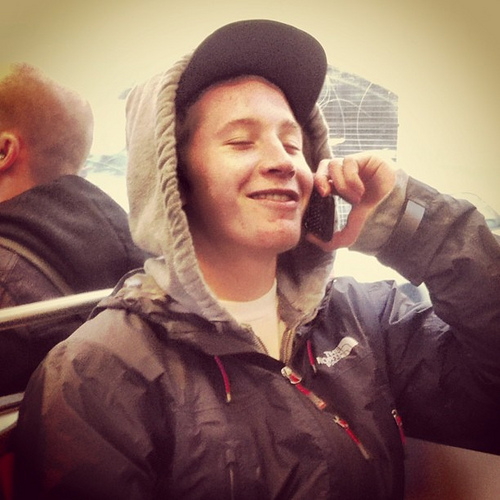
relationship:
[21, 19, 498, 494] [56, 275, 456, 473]
boy in jacket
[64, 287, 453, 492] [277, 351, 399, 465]
jacket has zippers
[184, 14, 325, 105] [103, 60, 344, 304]
cap under hood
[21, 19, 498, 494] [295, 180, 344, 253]
boy holding phone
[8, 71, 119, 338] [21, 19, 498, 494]
man back to boy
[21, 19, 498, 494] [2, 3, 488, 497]
boy picture picture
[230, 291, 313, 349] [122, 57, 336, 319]
shirt under hoodie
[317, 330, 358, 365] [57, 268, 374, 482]
logo on jacket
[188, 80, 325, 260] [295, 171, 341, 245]
man talking on phone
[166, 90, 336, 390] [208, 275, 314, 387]
person wearing shirt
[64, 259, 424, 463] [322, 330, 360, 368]
breaker with logo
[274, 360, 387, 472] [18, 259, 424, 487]
zipper on breaker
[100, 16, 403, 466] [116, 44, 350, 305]
man wearing hoodie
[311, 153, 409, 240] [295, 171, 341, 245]
hand holding phone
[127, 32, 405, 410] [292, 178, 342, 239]
man holding phone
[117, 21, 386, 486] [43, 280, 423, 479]
man wearing jacket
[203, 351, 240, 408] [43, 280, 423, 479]
string for jacket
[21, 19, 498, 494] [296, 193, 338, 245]
boy on phone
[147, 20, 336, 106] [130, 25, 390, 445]
hat worn by man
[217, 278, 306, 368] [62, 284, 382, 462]
shirt underneath jacket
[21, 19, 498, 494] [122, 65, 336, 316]
boy wearing hood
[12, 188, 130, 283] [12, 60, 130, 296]
hood for guy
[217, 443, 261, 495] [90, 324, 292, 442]
zipper in front of jacket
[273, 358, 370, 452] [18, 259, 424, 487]
zipper on breaker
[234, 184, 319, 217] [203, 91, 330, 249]
grin on face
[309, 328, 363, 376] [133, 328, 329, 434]
logo on jacket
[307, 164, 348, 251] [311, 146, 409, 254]
cell phone in hand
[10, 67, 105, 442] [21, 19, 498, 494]
man behind boy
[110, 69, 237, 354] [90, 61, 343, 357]
hoodie on head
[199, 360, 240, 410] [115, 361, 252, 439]
tie pull on jacket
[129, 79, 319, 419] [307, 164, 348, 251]
boy on cell phone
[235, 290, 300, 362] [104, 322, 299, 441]
t-shirt under jacket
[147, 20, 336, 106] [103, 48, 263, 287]
hat under hoodie